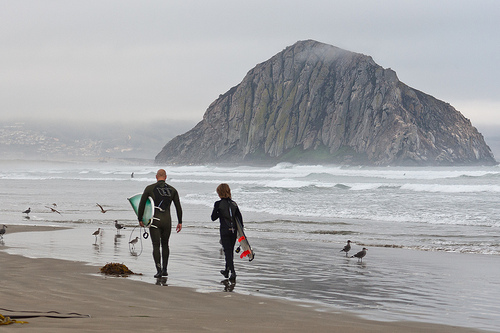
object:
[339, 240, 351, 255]
bird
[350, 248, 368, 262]
bird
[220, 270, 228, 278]
foot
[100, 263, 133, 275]
weed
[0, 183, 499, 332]
beach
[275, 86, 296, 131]
rock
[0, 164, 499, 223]
water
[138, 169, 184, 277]
man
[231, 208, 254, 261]
surfboard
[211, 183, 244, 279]
man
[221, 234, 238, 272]
trousers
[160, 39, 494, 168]
mountain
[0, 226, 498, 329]
shore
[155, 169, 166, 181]
bald head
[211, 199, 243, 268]
wetsuit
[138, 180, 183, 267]
wetsuit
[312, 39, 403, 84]
edge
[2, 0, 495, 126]
sky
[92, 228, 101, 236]
bird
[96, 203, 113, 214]
bird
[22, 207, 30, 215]
bird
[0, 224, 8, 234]
bird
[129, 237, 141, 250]
bird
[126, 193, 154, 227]
surboard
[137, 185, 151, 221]
arm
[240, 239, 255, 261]
part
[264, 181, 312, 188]
waves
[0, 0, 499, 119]
fog